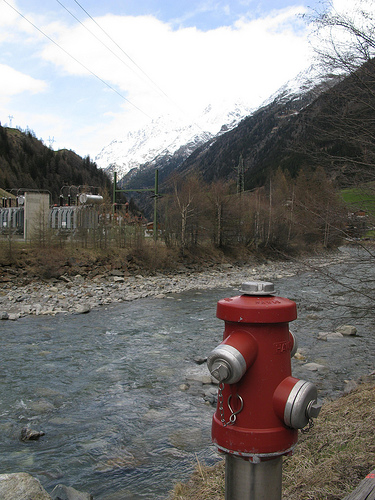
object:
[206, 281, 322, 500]
fire hydrant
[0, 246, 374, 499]
creek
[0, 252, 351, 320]
rocky area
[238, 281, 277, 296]
cap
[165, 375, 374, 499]
grass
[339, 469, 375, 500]
wood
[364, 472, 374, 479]
marking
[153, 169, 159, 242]
post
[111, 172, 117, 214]
post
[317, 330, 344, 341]
rock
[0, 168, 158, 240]
power station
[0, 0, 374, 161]
sky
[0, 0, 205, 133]
power lines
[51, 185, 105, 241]
transformer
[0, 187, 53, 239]
transformer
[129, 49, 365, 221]
mountain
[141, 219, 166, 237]
house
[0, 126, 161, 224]
hillside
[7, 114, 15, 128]
electrical pole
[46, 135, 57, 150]
electrical pole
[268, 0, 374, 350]
tree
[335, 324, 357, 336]
rock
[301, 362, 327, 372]
rock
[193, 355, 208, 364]
rock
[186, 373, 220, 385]
rock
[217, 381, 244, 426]
chain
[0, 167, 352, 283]
wooded area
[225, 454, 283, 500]
post